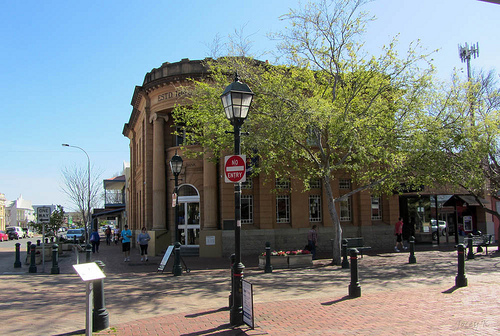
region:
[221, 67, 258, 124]
a street lamp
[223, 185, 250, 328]
a black sign post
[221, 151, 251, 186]
a red and white sign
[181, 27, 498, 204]
a leafy green tree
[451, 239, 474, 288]
a small black post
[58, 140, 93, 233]
a long curved light post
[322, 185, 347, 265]
the trunk of a tree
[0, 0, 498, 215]
a clear blue sky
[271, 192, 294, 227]
the window of a building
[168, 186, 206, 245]
the doors of a building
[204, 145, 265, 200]
a red and white no entry sign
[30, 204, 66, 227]
a one way sign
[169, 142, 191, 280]
a street lamp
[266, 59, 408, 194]
a green tree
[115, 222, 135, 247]
man wearing a blue shirt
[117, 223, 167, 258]
two people standing on the sidewalk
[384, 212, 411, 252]
man walking on the sidewalk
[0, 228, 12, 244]
a red car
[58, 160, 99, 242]
a tree without foliage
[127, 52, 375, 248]
an old building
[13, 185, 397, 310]
people walking on quiet street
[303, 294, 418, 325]
red brick pavement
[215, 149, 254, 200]
red and white sign on black pole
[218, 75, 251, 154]
street light at top of black pole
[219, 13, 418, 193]
tree leaves are bright green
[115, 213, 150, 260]
people on sidewalk near a tan building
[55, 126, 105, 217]
street light which hangs over street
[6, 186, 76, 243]
cars and buildings in the distance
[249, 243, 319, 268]
cement planter box with flowers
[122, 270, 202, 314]
shadow from the tree on ground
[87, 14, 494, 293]
Corner building on city street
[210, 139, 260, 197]
Red and white no entry sign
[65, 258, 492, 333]
Red cobblestone sidewalk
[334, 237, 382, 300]
black metal bollard with light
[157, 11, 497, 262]
Large green tree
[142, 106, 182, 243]
Two story Roman style column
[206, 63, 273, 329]
Black antique lamp post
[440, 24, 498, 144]
Tall white cell phone tower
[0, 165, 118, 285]
City street with cars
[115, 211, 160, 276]
Jogging man and woman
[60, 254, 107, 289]
white square stand on side walk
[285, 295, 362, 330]
red tiles on side walk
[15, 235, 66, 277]
black poles on side of street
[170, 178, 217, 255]
circular white door on building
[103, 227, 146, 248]
man wearing blue shirt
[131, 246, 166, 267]
white sneakers on woman's foot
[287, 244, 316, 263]
flowers in cement bed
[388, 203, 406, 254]
man walking on side of road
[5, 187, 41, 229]
large white building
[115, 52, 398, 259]
large brown building at end of street